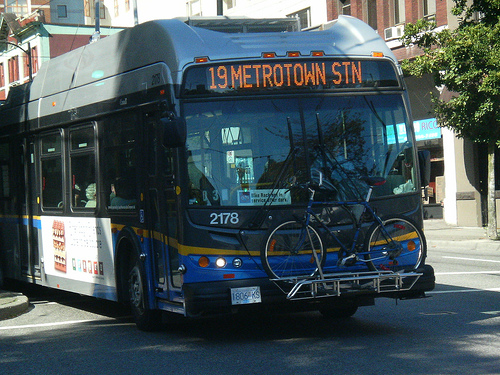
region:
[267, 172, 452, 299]
A bicycle in front of the bus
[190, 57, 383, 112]
19 METROTOWN STN is written on the bus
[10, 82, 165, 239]
Windows of the bus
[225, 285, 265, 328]
Number plate of the bus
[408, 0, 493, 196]
A tree in the road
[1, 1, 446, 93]
Buildings on the side of the road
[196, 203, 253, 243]
Number 2178 is written on the bus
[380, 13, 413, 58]
An AC in the building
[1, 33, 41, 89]
A street light in the road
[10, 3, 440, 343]
A bus on the road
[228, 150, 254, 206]
part of a windw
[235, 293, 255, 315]
edge of a plate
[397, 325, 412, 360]
part of a floor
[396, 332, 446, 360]
part f a shade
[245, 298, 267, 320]
edge of a bus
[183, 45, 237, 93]
bus number is 19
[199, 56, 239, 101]
bus number is 19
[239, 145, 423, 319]
a bike on bus front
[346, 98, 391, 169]
part of a window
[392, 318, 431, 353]
part of a shade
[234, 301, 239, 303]
part of a plate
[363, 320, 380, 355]
part of a floor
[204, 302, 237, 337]
edge of a bus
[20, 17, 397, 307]
this is a bus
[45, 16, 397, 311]
the bus is long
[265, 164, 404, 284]
this is a bike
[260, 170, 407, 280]
the bike is in front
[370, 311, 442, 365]
this is the road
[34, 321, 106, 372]
the road is tarmacked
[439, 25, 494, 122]
this is a tree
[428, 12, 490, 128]
the tree is leafy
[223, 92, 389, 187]
this is the front screen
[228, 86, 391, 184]
the front screen is clear